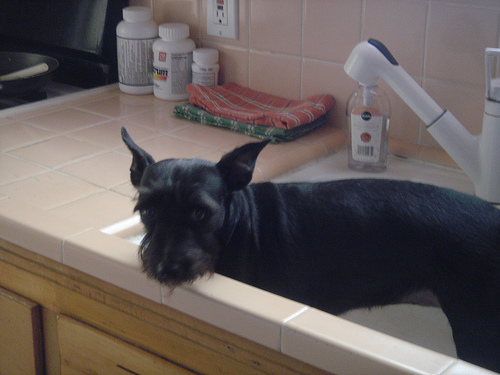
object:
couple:
[173, 82, 336, 144]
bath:
[123, 148, 499, 374]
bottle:
[345, 85, 391, 172]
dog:
[117, 126, 500, 374]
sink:
[101, 40, 500, 375]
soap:
[347, 114, 388, 172]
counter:
[0, 84, 346, 236]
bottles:
[115, 6, 219, 101]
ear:
[216, 138, 272, 193]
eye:
[140, 208, 147, 216]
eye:
[195, 206, 206, 220]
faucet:
[343, 38, 500, 203]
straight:
[131, 196, 215, 227]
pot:
[0, 50, 59, 98]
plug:
[205, 1, 238, 39]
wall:
[129, 0, 499, 150]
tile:
[7, 90, 189, 186]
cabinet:
[54, 312, 253, 374]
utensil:
[0, 63, 48, 81]